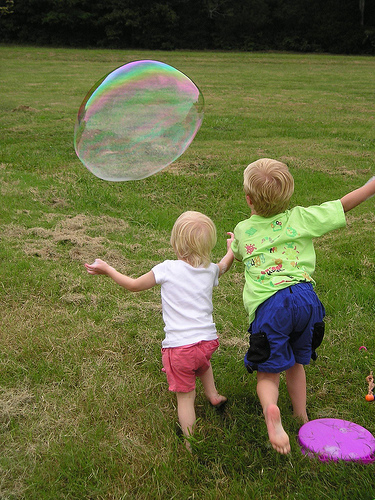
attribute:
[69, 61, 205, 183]
bubble — giant, mid air, big, huge, clear, large, floating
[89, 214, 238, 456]
girl — blonde, young, barefoot, playing, small, blond, running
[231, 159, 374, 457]
boy — blonde, barefoot, young, playing, older, running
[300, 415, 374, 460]
frisbee — purple, pink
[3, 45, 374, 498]
grass — green, burned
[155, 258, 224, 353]
shirt — white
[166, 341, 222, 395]
shorts — pink, red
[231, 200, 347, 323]
tshirt — green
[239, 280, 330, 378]
shorts — blue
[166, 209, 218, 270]
hair — blonde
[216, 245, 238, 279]
arm — extended out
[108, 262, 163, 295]
arm — extended out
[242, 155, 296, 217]
hair — blonde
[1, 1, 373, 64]
trees — distant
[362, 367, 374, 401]
object — orange